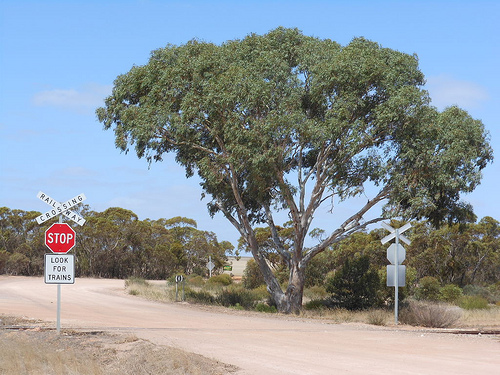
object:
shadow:
[453, 330, 497, 337]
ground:
[0, 270, 500, 375]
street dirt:
[253, 338, 315, 375]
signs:
[380, 221, 413, 325]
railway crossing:
[30, 185, 414, 341]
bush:
[323, 254, 389, 311]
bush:
[415, 215, 500, 288]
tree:
[92, 25, 495, 315]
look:
[46, 252, 69, 267]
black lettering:
[48, 257, 71, 281]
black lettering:
[40, 193, 84, 223]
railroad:
[0, 326, 500, 335]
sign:
[175, 275, 184, 283]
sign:
[206, 256, 216, 278]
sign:
[34, 190, 87, 336]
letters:
[46, 232, 73, 244]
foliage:
[193, 51, 267, 85]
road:
[2, 266, 484, 373]